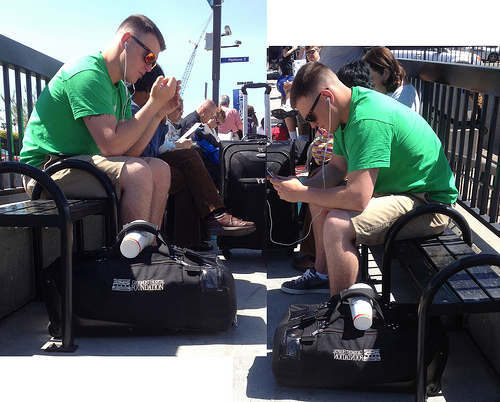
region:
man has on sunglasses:
[118, 28, 173, 76]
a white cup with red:
[98, 212, 167, 265]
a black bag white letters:
[91, 258, 180, 308]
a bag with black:
[63, 230, 258, 335]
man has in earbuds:
[116, 38, 156, 119]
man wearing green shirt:
[14, 30, 127, 202]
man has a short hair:
[282, 59, 328, 105]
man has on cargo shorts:
[335, 171, 440, 264]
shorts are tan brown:
[333, 155, 431, 273]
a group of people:
[132, 73, 254, 173]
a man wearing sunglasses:
[122, 17, 169, 82]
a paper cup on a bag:
[118, 219, 156, 263]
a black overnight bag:
[61, 239, 238, 345]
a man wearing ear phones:
[272, 83, 340, 208]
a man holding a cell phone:
[263, 153, 298, 208]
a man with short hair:
[112, 16, 172, 59]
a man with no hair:
[197, 93, 224, 125]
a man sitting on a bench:
[324, 81, 450, 287]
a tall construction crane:
[174, 16, 214, 123]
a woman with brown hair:
[369, 46, 404, 86]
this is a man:
[270, 58, 476, 382]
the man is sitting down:
[282, 50, 468, 393]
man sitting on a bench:
[291, 122, 497, 327]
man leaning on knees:
[277, 107, 410, 254]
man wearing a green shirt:
[323, 87, 450, 192]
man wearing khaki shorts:
[325, 178, 452, 258]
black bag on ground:
[269, 262, 445, 395]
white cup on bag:
[337, 265, 402, 349]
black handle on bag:
[320, 276, 400, 323]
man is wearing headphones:
[283, 82, 341, 264]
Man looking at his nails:
[17, 14, 182, 248]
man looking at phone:
[267, 60, 458, 310]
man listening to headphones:
[265, 53, 459, 317]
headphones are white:
[267, 94, 332, 245]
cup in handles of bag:
[269, 281, 451, 397]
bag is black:
[272, 282, 450, 400]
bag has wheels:
[274, 287, 451, 400]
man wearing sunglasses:
[267, 61, 459, 311]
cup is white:
[347, 280, 377, 331]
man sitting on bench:
[0, 12, 180, 352]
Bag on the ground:
[268, 279, 456, 397]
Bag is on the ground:
[263, 285, 453, 394]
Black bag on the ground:
[259, 286, 453, 396]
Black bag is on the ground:
[268, 281, 449, 393]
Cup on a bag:
[342, 273, 378, 336]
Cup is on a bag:
[342, 277, 383, 331]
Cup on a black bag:
[342, 277, 375, 332]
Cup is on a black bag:
[342, 272, 377, 329]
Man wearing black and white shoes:
[275, 262, 338, 297]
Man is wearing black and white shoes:
[273, 262, 339, 295]